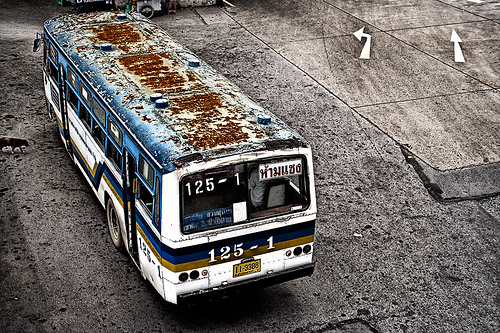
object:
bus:
[23, 7, 334, 311]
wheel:
[88, 205, 135, 249]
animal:
[0, 127, 32, 156]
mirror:
[22, 27, 54, 60]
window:
[171, 146, 317, 236]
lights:
[176, 260, 211, 285]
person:
[242, 167, 294, 210]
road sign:
[122, 4, 166, 23]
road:
[325, 128, 494, 306]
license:
[227, 246, 270, 286]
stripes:
[72, 146, 318, 263]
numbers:
[178, 164, 247, 202]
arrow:
[350, 22, 387, 67]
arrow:
[427, 23, 466, 68]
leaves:
[94, 1, 259, 149]